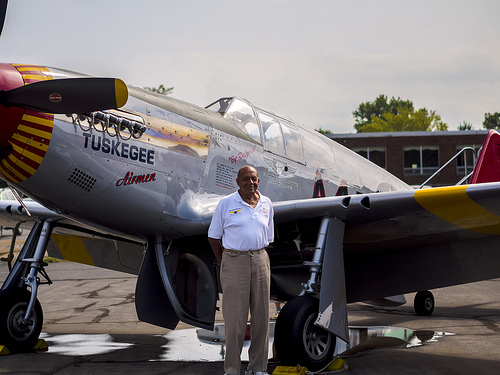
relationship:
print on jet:
[104, 154, 180, 225] [44, 89, 282, 179]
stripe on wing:
[416, 184, 482, 229] [346, 193, 499, 252]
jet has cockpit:
[0, 54, 498, 371] [109, 64, 271, 131]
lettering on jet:
[82, 132, 155, 165] [0, 54, 498, 371]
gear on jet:
[272, 289, 350, 372] [0, 54, 498, 371]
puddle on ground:
[69, 330, 216, 374] [75, 279, 153, 349]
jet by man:
[0, 54, 498, 371] [226, 167, 280, 370]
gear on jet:
[291, 268, 406, 350] [0, 54, 498, 371]